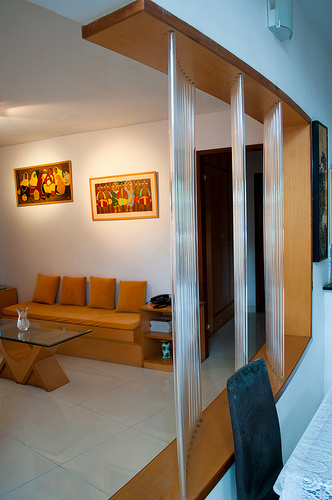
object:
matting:
[0, 305, 267, 499]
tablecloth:
[273, 379, 332, 499]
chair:
[226, 358, 285, 499]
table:
[273, 384, 332, 500]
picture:
[88, 172, 159, 221]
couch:
[3, 273, 148, 369]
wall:
[0, 104, 265, 308]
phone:
[151, 293, 171, 308]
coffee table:
[0, 317, 95, 392]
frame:
[196, 142, 265, 366]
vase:
[15, 305, 31, 330]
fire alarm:
[265, 0, 294, 46]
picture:
[312, 119, 330, 263]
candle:
[161, 340, 170, 360]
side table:
[139, 301, 206, 374]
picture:
[13, 159, 75, 209]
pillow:
[116, 280, 148, 311]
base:
[0, 338, 70, 393]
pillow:
[87, 275, 116, 309]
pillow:
[59, 276, 86, 307]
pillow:
[32, 272, 59, 305]